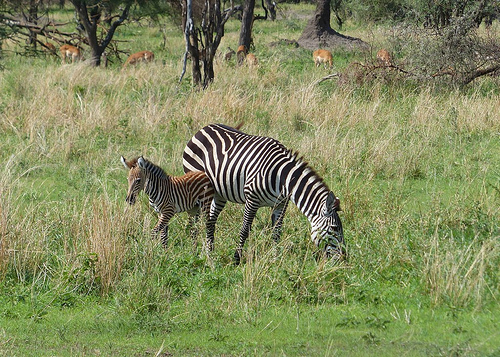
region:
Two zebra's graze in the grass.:
[117, 123, 359, 270]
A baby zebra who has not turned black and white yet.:
[123, 153, 218, 256]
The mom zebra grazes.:
[181, 120, 357, 269]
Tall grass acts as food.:
[332, 90, 488, 335]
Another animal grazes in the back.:
[117, 43, 156, 75]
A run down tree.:
[171, 3, 228, 91]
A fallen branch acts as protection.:
[327, 52, 498, 87]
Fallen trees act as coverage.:
[2, 5, 132, 72]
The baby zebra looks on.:
[117, 154, 143, 208]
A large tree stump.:
[302, 5, 365, 55]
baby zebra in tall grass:
[117, 150, 215, 242]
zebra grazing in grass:
[183, 112, 353, 275]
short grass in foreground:
[0, 278, 496, 355]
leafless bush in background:
[317, 5, 497, 92]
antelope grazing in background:
[309, 45, 339, 70]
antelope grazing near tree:
[114, 43, 156, 70]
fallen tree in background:
[1, 6, 129, 68]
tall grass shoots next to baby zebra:
[62, 193, 156, 301]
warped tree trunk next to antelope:
[297, 0, 375, 54]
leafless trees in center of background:
[178, 0, 233, 92]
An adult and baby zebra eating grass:
[114, 119, 349, 281]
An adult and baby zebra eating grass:
[113, 112, 349, 277]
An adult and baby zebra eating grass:
[115, 117, 348, 275]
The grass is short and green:
[48, 294, 458, 354]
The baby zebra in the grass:
[115, 144, 217, 251]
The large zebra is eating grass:
[181, 114, 380, 285]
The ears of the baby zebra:
[118, 148, 148, 170]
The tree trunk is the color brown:
[177, 1, 227, 91]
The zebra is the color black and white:
[186, 123, 352, 251]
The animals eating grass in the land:
[44, 27, 449, 102]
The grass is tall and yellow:
[22, 66, 463, 148]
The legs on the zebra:
[228, 200, 291, 268]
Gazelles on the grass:
[33, 31, 409, 78]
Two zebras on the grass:
[115, 117, 351, 282]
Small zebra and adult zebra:
[108, 121, 350, 275]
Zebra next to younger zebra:
[116, 123, 350, 277]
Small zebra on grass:
[118, 153, 215, 262]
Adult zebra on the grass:
[180, 122, 348, 272]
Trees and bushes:
[1, 1, 499, 91]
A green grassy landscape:
[1, 12, 498, 354]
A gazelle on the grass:
[308, 45, 334, 70]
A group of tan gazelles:
[28, 29, 470, 78]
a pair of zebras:
[116, 126, 371, 260]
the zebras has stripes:
[179, 114, 360, 270]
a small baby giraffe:
[106, 143, 228, 265]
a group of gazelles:
[40, 20, 400, 85]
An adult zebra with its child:
[124, 124, 345, 269]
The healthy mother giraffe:
[184, 124, 357, 261]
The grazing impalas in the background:
[36, 40, 403, 75]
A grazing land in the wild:
[0, 0, 498, 354]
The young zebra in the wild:
[116, 158, 215, 252]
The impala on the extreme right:
[377, 45, 396, 69]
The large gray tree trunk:
[295, 1, 371, 51]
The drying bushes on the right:
[343, 21, 498, 92]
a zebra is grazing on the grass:
[178, 120, 346, 272]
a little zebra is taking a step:
[123, 158, 211, 265]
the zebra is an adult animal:
[181, 120, 346, 275]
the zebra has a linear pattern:
[182, 118, 348, 269]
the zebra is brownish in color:
[122, 155, 212, 271]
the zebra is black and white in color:
[183, 121, 345, 279]